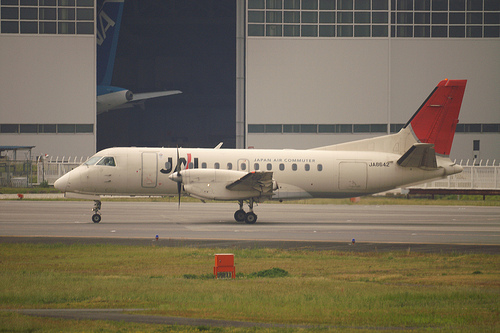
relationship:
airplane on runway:
[53, 79, 468, 223] [2, 199, 499, 244]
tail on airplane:
[404, 77, 469, 159] [53, 79, 468, 223]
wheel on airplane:
[244, 212, 257, 224] [53, 79, 468, 223]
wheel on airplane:
[232, 207, 249, 224] [53, 79, 468, 223]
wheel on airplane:
[90, 213, 104, 223] [53, 79, 468, 223]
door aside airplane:
[142, 150, 159, 188] [53, 79, 468, 223]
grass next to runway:
[287, 251, 462, 310] [27, 202, 498, 236]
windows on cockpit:
[79, 148, 116, 165] [72, 143, 127, 170]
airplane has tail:
[53, 79, 468, 223] [406, 73, 473, 175]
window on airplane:
[290, 163, 298, 171] [53, 79, 468, 223]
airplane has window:
[53, 79, 468, 223] [266, 160, 271, 171]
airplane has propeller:
[53, 79, 468, 223] [170, 137, 187, 194]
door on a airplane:
[141, 153, 157, 188] [53, 79, 468, 223]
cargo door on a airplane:
[337, 162, 367, 190] [53, 79, 468, 223]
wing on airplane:
[226, 171, 274, 192] [1, 48, 490, 263]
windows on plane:
[226, 149, 338, 184] [9, 66, 494, 236]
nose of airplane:
[43, 177, 71, 194] [30, 78, 471, 230]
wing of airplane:
[174, 160, 361, 246] [53, 79, 468, 223]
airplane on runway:
[50, 67, 491, 272] [46, 165, 472, 258]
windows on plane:
[172, 152, 343, 177] [33, 72, 497, 272]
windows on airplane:
[205, 157, 331, 171] [53, 79, 468, 223]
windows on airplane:
[197, 155, 346, 178] [53, 79, 468, 223]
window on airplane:
[238, 158, 250, 170] [53, 79, 468, 223]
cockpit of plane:
[53, 150, 139, 203] [57, 125, 487, 221]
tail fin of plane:
[348, 43, 472, 224] [37, 117, 492, 249]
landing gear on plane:
[242, 183, 297, 219] [33, 71, 499, 248]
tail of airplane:
[402, 65, 479, 205] [61, 97, 486, 281]